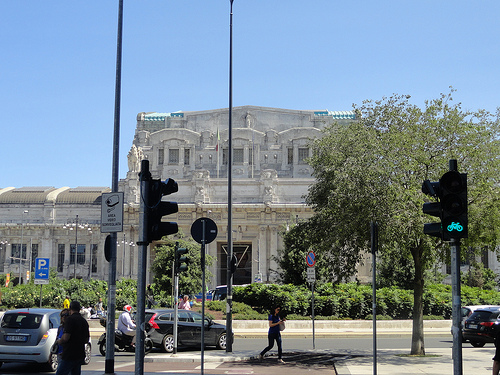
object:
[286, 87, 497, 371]
tree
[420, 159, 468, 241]
light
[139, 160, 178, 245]
street light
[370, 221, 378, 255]
sign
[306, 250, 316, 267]
sign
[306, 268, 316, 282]
sign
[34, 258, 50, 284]
sign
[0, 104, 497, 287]
building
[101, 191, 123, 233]
sign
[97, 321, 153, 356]
motorcycle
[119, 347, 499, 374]
sidewalk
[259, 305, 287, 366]
lady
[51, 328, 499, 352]
street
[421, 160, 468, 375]
lamp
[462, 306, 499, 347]
vehicle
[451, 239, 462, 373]
pole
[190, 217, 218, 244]
sign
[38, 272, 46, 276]
arrow